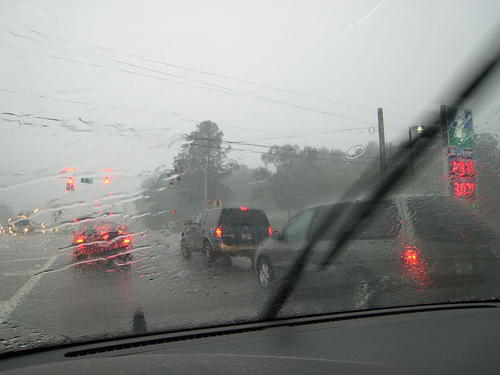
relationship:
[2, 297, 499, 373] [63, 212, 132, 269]
dashboard of a car car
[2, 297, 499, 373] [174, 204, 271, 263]
dashboard of a car car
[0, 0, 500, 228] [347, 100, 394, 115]
clouds in blue sky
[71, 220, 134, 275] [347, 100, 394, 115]
car in blue sky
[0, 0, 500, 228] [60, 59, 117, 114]
clouds in blue sky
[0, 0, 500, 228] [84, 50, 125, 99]
clouds in blue sky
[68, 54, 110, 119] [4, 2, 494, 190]
clouds in blue sky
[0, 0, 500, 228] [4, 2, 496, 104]
clouds in blue sky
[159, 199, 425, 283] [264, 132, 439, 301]
banana in box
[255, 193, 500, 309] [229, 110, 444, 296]
banana in box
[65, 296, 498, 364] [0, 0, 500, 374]
vent on inside front of a car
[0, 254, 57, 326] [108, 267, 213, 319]
lines drawn on pavement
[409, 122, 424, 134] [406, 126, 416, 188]
street light high up on a pole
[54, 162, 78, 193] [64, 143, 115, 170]
overhead light in air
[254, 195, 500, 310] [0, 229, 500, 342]
car on pavement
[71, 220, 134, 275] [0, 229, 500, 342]
car on pavement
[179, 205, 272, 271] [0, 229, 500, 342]
car on pavement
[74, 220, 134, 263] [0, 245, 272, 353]
car on road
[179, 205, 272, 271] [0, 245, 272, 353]
car on road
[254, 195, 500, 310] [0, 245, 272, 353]
car on road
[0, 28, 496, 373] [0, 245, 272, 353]
car on road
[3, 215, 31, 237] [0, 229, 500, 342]
car on pavement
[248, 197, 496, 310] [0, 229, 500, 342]
car on pavement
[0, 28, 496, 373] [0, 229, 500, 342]
car on pavement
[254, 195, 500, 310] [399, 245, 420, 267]
car with brake light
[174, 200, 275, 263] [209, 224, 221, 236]
car with brake light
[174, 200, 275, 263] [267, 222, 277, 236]
car with brake light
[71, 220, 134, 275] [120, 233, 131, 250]
car with brake light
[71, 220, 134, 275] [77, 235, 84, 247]
car with brake light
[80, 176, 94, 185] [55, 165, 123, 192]
sign in between traffic lights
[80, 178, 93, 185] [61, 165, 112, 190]
sign on traffic light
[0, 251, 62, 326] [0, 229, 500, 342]
lines on pavement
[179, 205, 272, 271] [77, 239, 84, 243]
car with brake light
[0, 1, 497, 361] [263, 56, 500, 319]
windshield has wiper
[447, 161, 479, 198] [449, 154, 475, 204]
sign with numbers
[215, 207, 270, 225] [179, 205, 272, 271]
window of car